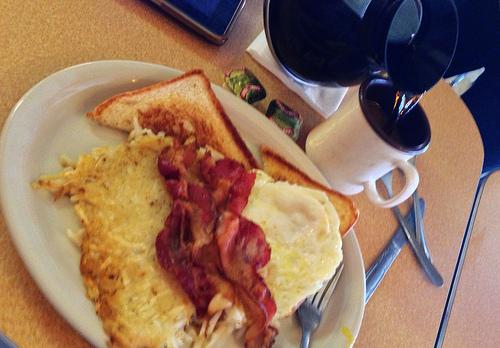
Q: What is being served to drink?
A: Coffee.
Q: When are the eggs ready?
A: Now.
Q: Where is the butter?
A: Next to the plate.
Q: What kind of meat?
A: Bacon.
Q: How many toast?
A: 2 slices.